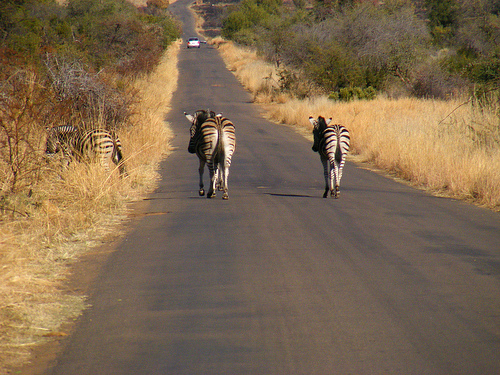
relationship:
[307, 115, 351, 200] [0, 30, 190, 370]
zebra walking into grass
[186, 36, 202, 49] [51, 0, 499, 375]
car in road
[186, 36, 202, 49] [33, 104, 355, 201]
car in front of zebras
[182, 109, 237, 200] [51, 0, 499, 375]
zebra on road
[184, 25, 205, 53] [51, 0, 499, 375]
car on road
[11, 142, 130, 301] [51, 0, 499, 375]
grass on road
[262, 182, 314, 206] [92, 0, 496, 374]
dark spot in road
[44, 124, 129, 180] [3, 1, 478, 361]
zebra walking outside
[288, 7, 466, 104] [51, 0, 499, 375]
trees on side of road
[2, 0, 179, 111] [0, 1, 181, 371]
trees on side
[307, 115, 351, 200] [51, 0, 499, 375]
zebra walking down road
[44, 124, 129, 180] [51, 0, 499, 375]
zebra to side of road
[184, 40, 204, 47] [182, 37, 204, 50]
lights on car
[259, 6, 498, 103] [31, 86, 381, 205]
overgrowth ahead of zebras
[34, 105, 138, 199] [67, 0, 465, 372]
zebra feeding to side of road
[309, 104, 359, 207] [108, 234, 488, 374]
zebra in road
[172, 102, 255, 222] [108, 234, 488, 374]
zebra in road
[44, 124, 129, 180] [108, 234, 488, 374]
zebra in road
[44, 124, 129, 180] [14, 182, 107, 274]
zebra in grass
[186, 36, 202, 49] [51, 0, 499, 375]
car on road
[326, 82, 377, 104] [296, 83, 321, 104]
bushes in plants